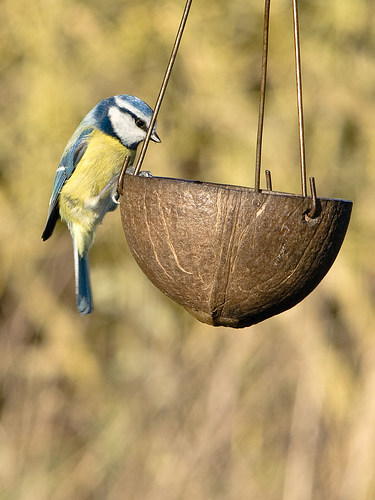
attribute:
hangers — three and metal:
[159, 101, 305, 122]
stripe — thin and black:
[117, 108, 154, 135]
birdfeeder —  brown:
[146, 234, 297, 298]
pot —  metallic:
[167, 223, 325, 307]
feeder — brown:
[124, 187, 339, 358]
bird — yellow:
[41, 87, 159, 313]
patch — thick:
[197, 185, 255, 319]